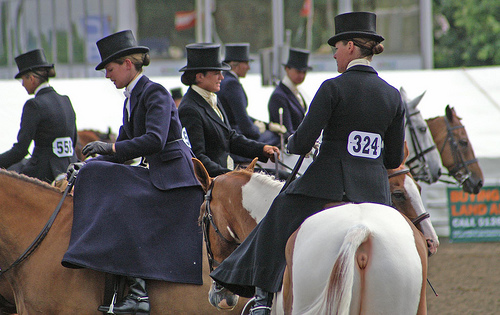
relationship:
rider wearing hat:
[208, 10, 408, 313] [328, 10, 383, 44]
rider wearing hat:
[0, 45, 78, 182] [10, 47, 55, 77]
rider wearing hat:
[177, 40, 279, 177] [177, 38, 232, 73]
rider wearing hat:
[217, 39, 284, 147] [221, 42, 255, 66]